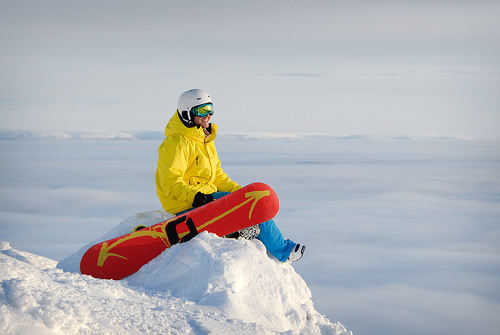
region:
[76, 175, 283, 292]
red and yellow snowboard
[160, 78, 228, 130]
white helmet on the head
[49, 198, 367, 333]
a mound of snow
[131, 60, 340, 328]
person sitting on the snow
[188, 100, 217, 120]
goggles on the face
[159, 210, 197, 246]
black square on the bottom of the snowboard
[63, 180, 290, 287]
snowboard laying in the snow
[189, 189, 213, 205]
black glove on the hand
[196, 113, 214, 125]
smile on the face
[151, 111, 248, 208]
bright yellow jacket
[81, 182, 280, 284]
Red underside of a snowboard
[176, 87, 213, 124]
White helmet and reflective goggles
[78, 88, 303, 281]
A snowboarder sitting on a pile of snow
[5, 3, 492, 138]
A dull, grayish sky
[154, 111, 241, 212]
A bright, yellow jacket.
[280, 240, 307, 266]
A white shoe being worn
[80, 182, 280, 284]
A red snowboard with yellow arrows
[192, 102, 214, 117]
Reflective tint on protective goggles.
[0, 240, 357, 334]
Fluffy white snow on a hill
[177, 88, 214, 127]
A white helmet on a head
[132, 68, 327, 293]
person sitting in the snow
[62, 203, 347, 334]
a mound of snow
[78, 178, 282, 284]
red and yellow snowboard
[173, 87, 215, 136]
white helmet on the head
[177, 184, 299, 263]
bright blue snow pants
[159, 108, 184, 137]
hood on the back of the jacket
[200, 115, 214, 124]
smile on the face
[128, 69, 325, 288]
this is a person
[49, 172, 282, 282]
this is a surfboard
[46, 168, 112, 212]
this is a body of water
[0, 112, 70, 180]
this is a body of water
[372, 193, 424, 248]
this is a body of water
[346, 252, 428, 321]
this is a body of water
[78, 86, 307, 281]
person is holding a red snowboard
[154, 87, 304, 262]
person is wearing a yellow jacket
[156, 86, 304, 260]
person is wearing a white helmet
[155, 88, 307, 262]
person is wearing blue pants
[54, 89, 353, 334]
person sitting on a mound of snow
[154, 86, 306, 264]
person is wearing a white shoe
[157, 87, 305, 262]
person is wearing goggles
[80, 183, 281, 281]
black and yellow design on snowboard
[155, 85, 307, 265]
person is smiling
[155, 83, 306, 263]
person is wearing a black glove